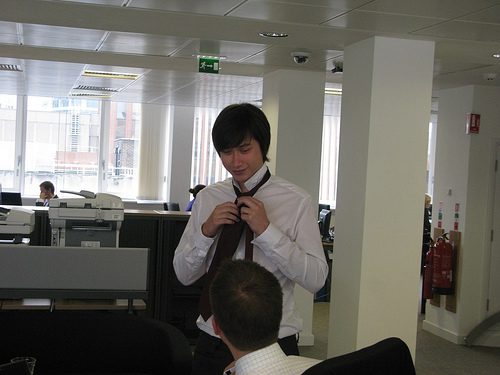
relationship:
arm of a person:
[170, 206, 217, 292] [168, 93, 328, 354]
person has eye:
[165, 102, 333, 373] [236, 140, 251, 159]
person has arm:
[165, 102, 333, 373] [172, 190, 214, 288]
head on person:
[197, 260, 300, 356] [197, 254, 325, 374]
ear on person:
[209, 314, 219, 339] [197, 254, 325, 374]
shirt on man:
[171, 177, 343, 277] [173, 100, 328, 372]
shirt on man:
[171, 177, 343, 277] [156, 81, 361, 348]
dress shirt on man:
[175, 164, 332, 349] [173, 100, 328, 372]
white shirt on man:
[171, 160, 329, 340] [173, 100, 328, 372]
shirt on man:
[171, 177, 343, 277] [174, 106, 436, 374]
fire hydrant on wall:
[421, 232, 459, 308] [423, 86, 495, 342]